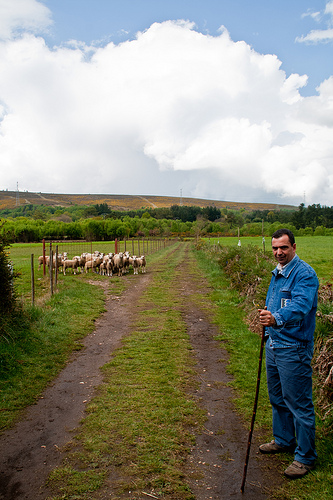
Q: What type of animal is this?
A: Sheep.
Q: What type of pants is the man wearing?
A: Jeans.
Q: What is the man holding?
A: A stick.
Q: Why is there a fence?
A: To pen the sheep.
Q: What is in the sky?
A: Clouds.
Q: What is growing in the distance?
A: Trees.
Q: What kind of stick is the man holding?
A: A walking stick.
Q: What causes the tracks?
A: Tires.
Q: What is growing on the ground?
A: Grass.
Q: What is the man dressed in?
A: Blue clothing.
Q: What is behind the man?
A: A field.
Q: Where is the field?
A: Behind the man.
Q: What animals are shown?
A: Sheep.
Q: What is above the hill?
A: Clouds.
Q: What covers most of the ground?
A: Grass.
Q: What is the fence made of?
A: Wire.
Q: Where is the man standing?
A: Grass.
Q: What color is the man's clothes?
A: Blue.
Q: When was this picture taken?
A: Daytime.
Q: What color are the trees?
A: Green.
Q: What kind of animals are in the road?
A: Sheep.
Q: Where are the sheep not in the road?
A: Inside gate.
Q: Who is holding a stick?
A: The man.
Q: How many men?
A: One.